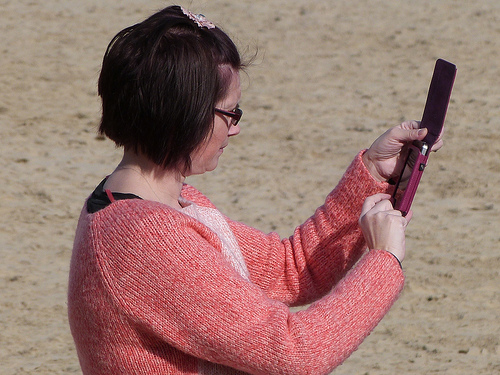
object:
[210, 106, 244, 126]
eye glasses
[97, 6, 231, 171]
bob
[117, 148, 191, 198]
womans neck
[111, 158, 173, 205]
necklace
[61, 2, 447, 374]
lady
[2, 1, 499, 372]
sand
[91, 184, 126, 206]
shirt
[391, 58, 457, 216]
cell phone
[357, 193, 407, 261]
hand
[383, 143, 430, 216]
case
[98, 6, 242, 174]
hair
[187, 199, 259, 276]
shirt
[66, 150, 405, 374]
red sweater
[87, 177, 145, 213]
black shirt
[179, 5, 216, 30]
bow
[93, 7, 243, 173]
head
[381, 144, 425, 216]
system